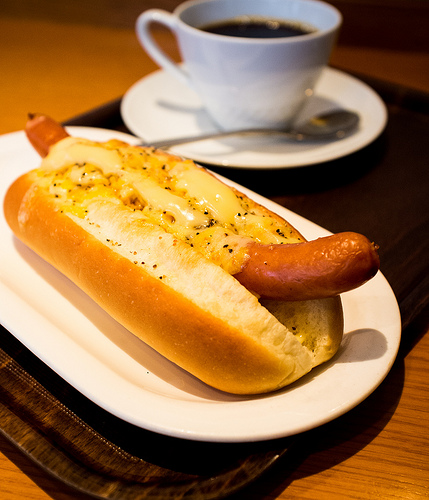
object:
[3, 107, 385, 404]
hot dog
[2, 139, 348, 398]
roll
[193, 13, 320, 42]
coffee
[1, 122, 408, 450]
plate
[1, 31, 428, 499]
place mat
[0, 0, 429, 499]
table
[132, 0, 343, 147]
cup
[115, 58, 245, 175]
saucer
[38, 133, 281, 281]
cheese